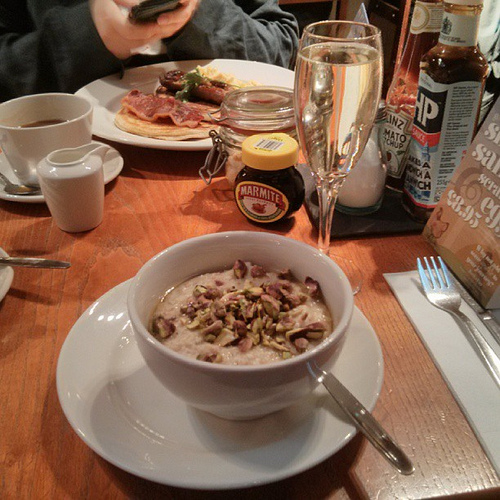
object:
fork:
[413, 253, 500, 393]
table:
[1, 91, 498, 500]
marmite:
[232, 131, 304, 230]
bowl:
[121, 230, 355, 427]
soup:
[147, 260, 334, 363]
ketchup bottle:
[378, 0, 442, 197]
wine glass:
[293, 19, 383, 301]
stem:
[314, 189, 336, 260]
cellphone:
[126, 0, 180, 26]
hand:
[89, 0, 159, 65]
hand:
[153, 0, 198, 40]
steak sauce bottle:
[397, 0, 489, 226]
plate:
[71, 58, 295, 148]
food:
[157, 68, 234, 104]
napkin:
[379, 269, 498, 481]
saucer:
[0, 139, 124, 201]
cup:
[0, 88, 92, 188]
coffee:
[11, 117, 67, 127]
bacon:
[116, 88, 205, 130]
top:
[300, 18, 383, 47]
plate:
[50, 277, 382, 491]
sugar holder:
[197, 88, 295, 195]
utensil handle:
[3, 254, 73, 266]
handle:
[453, 309, 500, 391]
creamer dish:
[34, 142, 106, 234]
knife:
[445, 264, 499, 349]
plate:
[0, 244, 14, 303]